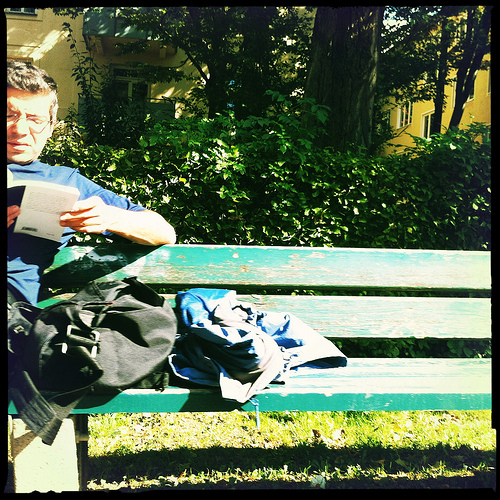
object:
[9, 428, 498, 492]
shadow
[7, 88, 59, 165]
face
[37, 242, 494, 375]
rail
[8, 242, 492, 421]
wood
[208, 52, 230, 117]
trunk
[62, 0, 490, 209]
tree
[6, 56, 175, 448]
man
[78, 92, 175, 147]
wndow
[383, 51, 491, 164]
paint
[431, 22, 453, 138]
trunk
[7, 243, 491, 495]
bench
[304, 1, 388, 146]
trunk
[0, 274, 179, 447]
bag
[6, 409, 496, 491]
ground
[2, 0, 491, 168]
house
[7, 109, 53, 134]
glasses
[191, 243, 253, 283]
paint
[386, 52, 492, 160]
wall